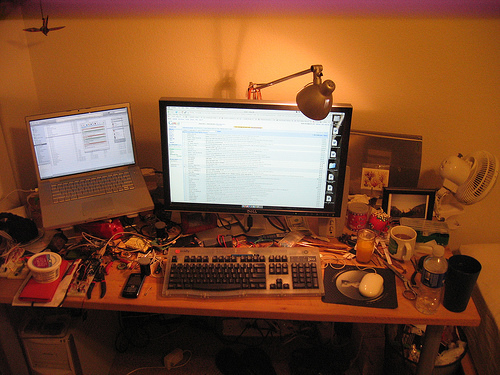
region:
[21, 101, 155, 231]
a grey open laptop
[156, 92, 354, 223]
black computer monitor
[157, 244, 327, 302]
grey computer keyboard on a desk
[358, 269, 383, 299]
a white computer mouse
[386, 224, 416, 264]
white mug with coffee in it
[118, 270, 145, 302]
a black cell phone on a desk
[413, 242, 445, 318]
an empty water bottle on a desk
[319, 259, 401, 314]
black mouse pad with a white mouse on it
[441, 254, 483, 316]
a black cup on the corner of a desk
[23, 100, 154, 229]
this is a laptop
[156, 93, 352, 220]
this is a television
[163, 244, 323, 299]
this is a keyboard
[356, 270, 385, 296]
this is a mouse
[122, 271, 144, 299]
this is a mobile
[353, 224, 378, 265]
this is a glass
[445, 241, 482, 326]
this is a glass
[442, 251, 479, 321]
this is a black glass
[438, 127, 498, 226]
this is a fan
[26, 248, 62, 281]
this is a tin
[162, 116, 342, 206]
this is a monitor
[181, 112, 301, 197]
the monitor is on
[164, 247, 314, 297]
this is the keyboard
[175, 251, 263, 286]
the buttons are black in color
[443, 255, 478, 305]
this is a cup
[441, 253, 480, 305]
the cup is black in color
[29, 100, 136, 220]
this is a laptop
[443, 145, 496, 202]
this is a fan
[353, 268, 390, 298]
this is a mouse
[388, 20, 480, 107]
this is the wall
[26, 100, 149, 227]
A silver laptop on a desk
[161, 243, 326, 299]
A mechanical keyboard with black keys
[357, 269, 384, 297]
A white mouse on a mousepad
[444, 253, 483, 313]
A black cup on the desk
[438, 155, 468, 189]
The back side of an oscillating fan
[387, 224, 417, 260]
A white mug full of coffee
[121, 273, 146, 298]
A "bar" style cellular phone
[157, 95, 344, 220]
A silver and black computer monitor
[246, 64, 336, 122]
A desk lamp leaning over a monitor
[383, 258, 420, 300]
Scissors laid on a desk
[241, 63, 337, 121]
lamp points at monitor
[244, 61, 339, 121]
lamp hangs over monitor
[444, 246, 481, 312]
cup is on desk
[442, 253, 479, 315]
cup is on edge of desk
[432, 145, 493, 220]
fan is on desk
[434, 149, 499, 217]
fan is on edge of desk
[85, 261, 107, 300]
pliers are on desk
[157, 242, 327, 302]
keyboard is on desk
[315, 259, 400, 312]
mousepad is on desk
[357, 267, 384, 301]
mouse is on mousepad